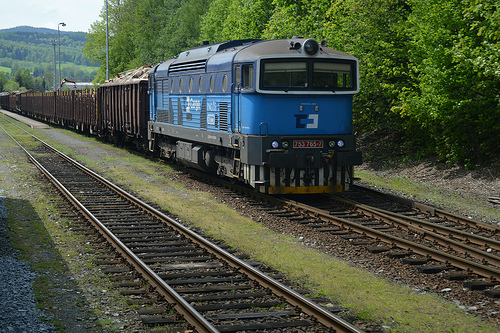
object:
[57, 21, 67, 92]
lamp post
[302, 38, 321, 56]
guide light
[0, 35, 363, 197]
train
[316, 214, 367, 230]
tracks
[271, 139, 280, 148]
headlight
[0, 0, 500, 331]
picture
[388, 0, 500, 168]
bushes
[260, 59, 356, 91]
windshield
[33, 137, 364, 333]
track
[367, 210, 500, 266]
tracks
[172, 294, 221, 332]
tracks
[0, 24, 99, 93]
mountain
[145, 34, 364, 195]
blue train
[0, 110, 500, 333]
grass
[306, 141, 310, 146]
numbers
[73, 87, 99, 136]
train compartment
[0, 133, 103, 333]
sidewalk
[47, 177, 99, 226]
tracks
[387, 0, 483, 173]
tree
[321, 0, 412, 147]
tree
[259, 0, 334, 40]
tree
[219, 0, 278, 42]
tree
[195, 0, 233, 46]
tree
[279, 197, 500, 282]
track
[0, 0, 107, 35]
sky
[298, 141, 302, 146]
numbers